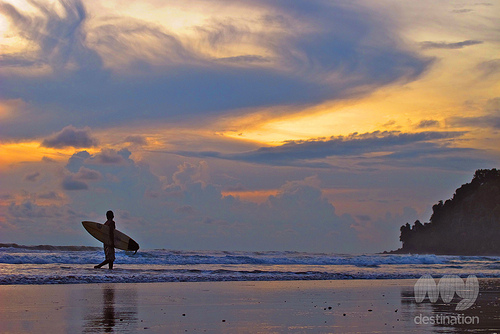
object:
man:
[94, 210, 116, 271]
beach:
[0, 277, 500, 334]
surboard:
[81, 221, 140, 255]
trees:
[376, 168, 500, 256]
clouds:
[0, 0, 320, 90]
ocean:
[0, 243, 500, 284]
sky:
[0, 0, 499, 254]